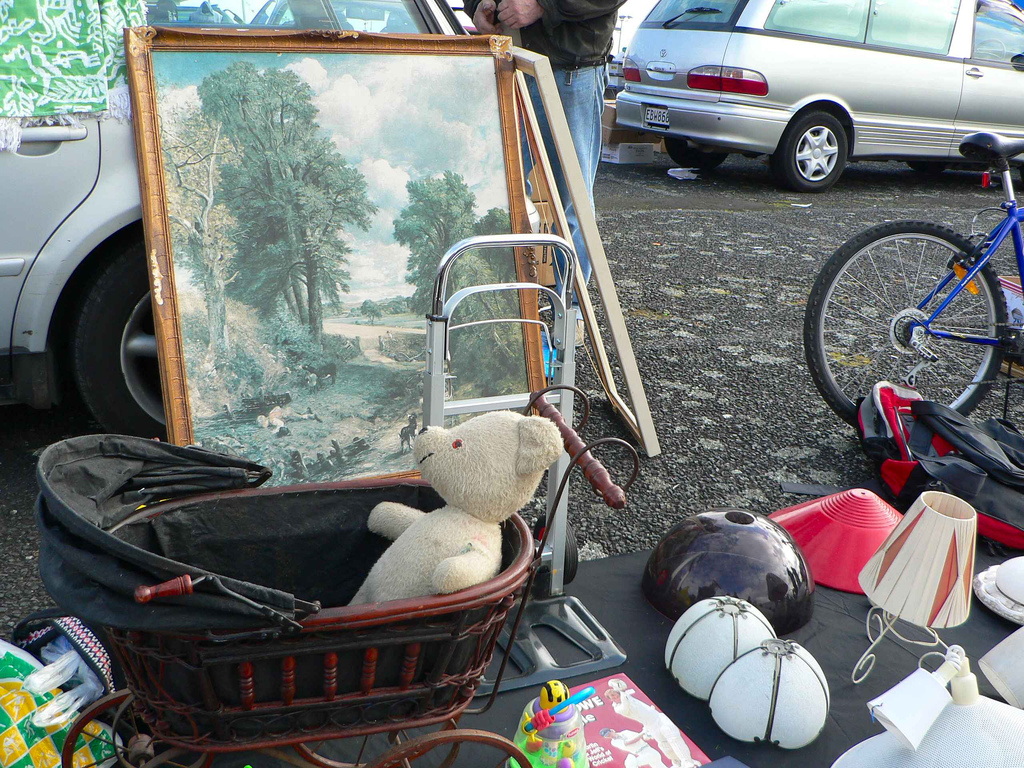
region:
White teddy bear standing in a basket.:
[322, 412, 561, 606]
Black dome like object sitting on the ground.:
[637, 505, 814, 638]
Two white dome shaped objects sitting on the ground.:
[656, 594, 831, 750]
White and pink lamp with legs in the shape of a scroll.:
[847, 483, 980, 689]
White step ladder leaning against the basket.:
[423, 236, 585, 597]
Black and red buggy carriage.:
[16, 388, 650, 765]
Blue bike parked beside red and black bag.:
[808, 125, 1023, 465]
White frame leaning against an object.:
[511, 43, 667, 456]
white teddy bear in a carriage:
[345, 401, 554, 598]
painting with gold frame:
[101, 14, 557, 439]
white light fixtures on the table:
[672, 594, 812, 743]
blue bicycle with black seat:
[808, 120, 1023, 416]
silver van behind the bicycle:
[632, 10, 1022, 195]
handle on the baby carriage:
[522, 374, 668, 518]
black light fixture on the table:
[642, 477, 816, 634]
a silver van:
[620, 9, 1020, 153]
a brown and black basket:
[56, 468, 525, 722]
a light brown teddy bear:
[376, 411, 532, 574]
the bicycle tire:
[802, 231, 998, 405]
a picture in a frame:
[132, 92, 540, 435]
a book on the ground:
[527, 689, 712, 760]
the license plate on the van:
[645, 101, 672, 122]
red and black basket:
[64, 456, 555, 735]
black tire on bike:
[780, 203, 1019, 432]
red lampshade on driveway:
[780, 471, 921, 583]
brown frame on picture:
[143, 42, 573, 485]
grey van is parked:
[617, 3, 1000, 177]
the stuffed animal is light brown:
[345, 411, 564, 605]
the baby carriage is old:
[27, 385, 638, 765]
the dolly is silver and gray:
[424, 233, 631, 701]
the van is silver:
[612, 0, 1018, 187]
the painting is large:
[125, 22, 549, 485]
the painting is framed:
[122, 19, 544, 504]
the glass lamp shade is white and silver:
[706, 638, 830, 752]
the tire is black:
[770, 102, 850, 191]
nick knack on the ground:
[696, 627, 839, 751]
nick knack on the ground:
[661, 586, 773, 705]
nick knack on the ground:
[655, 507, 801, 654]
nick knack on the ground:
[838, 472, 976, 714]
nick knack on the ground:
[769, 482, 922, 601]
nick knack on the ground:
[974, 545, 1019, 613]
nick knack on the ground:
[501, 650, 604, 764]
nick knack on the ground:
[23, 577, 118, 737]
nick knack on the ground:
[867, 626, 1020, 766]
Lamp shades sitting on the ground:
[622, 470, 999, 752]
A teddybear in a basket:
[326, 397, 586, 612]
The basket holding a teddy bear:
[32, 423, 546, 766]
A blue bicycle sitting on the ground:
[790, 127, 1022, 448]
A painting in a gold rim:
[116, 12, 559, 547]